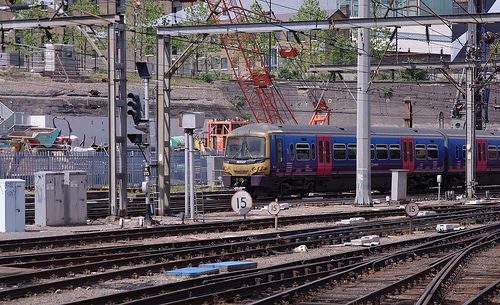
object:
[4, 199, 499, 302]
train track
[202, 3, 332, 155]
vehicle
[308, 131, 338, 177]
doors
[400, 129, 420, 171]
doors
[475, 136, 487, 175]
doors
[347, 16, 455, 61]
wall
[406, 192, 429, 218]
ground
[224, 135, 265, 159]
windshield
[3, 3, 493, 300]
railroad station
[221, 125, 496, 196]
train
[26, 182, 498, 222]
track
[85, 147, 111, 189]
fence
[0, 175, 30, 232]
boxes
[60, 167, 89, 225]
box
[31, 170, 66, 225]
box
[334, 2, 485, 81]
building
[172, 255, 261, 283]
panels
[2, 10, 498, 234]
structure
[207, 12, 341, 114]
red structure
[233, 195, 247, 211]
15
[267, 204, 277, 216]
15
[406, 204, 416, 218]
15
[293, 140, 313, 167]
window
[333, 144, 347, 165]
window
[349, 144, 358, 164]
window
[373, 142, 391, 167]
window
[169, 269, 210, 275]
cover